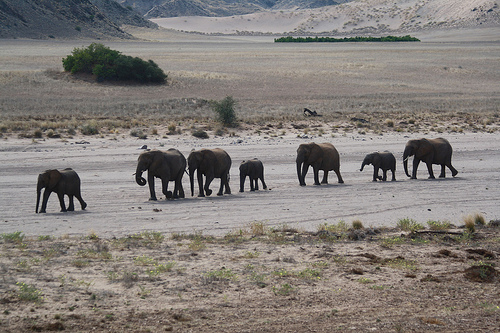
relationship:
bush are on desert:
[58, 38, 174, 86] [4, 20, 493, 123]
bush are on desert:
[58, 38, 174, 86] [4, 25, 497, 132]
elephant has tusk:
[399, 133, 459, 178] [401, 150, 414, 161]